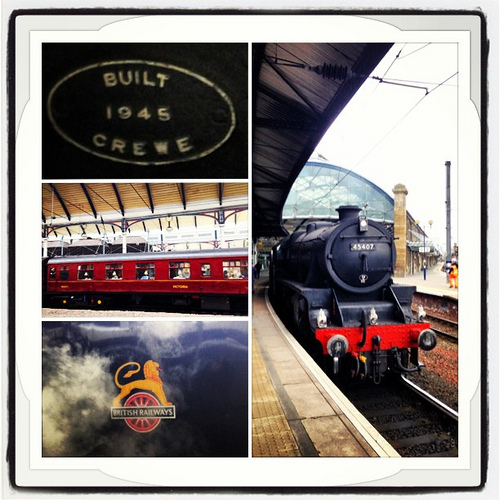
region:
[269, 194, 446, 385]
train at the station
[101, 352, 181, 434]
logo on a train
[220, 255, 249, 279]
window of a train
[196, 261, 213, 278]
window of a train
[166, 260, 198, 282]
window of a train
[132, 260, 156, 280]
window of a train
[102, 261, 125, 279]
window of a train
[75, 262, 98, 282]
window of a train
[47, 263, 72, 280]
window of a train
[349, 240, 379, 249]
numbers on a train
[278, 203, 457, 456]
a train on the tracks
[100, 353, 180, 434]
a lion icon on the train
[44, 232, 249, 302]
a train at the station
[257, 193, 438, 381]
a train next to the platform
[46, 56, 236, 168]
year the train was built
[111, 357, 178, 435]
name of the train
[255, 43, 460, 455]
train station is outside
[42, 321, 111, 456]
steam is coming from the train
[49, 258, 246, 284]
people are on the train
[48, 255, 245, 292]
the train is red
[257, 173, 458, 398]
a train passing by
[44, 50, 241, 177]
a steel plate with built date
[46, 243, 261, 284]
windows of a train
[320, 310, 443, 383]
front bumper of a train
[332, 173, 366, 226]
a steam pipe of a train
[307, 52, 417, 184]
power lines of a train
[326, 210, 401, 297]
front engine of a train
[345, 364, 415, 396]
wheel of a train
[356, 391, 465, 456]
railroads on ground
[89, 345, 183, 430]
logo printed on train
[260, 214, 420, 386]
old steam train at station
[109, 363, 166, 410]
yellow lion on logo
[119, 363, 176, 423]
british airways logo on surface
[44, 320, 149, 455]
white clouds reflecting on surface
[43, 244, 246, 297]
red passenger train car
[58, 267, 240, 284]
row of windows on train car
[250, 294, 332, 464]
concrete boarding platform at station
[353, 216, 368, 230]
small headlight of train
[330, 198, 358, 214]
smoke stack on train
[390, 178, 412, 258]
concrete pillar in background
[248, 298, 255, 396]
Black and tan side walk by the train.Black and tan side walk by the train.